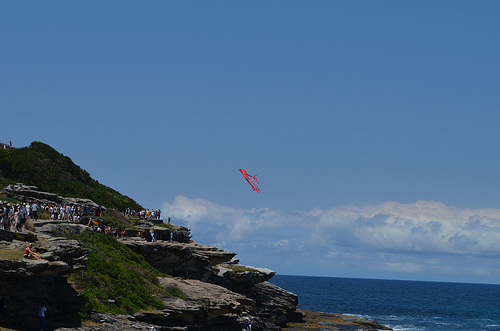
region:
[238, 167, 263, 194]
a red kite flying in the air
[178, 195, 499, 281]
some white clouds floating in the air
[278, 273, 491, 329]
the ocean next to the hill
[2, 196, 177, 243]
people standing around watching the kite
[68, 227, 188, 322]
the green grass on the hill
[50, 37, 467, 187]
a bunch of blue sky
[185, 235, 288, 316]
the rocks sticking out of the hill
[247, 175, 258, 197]
the long tail of the kite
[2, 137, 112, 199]
the top of the hill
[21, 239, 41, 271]
a person sitting on the hill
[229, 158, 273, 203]
red kite flying in sky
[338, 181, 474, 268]
large white cloud in blue sky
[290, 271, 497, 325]
blue water of ocean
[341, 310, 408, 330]
white wave in blue ocean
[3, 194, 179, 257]
group of people on rock formation in front of ocean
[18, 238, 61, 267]
person sitting alone on rock facing ocean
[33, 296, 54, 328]
person in rock cavern in front of ocean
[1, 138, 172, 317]
tall grass covered rock formation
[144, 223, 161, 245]
person on rock formation walking away from ocean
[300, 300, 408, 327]
flat land plateau in front of ocean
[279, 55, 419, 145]
The sky is blue.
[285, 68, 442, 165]
The sky is clear.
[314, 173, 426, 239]
Clouds are in the sky.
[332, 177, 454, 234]
The clouds are blue and white.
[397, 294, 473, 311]
The water is blue.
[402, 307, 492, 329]
Foam is in the water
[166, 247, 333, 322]
Rocks are showing.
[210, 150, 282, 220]
A kite is flying.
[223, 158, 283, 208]
The kie is red.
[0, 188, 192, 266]
People are watching.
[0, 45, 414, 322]
people on top of cliff by water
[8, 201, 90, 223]
large group of people standing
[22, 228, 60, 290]
person laying on top of cliff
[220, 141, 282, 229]
red kite being flown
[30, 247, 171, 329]
grass on side of cliff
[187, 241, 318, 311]
rock jettisoned out from cliff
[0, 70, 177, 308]
cliff mixed with grassy hill behind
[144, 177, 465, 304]
clouds in background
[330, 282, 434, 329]
blue ocean water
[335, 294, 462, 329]
white water from waves breaking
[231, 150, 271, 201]
red kite flying in blue sky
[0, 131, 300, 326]
people standing on cliffs watching a kite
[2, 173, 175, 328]
many people on cliff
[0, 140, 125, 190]
forest on top of cliff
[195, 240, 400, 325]
large cliff over the ocean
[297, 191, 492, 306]
clouds over the ocean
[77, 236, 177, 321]
grass growing on the cliffs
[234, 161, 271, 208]
red streamer flying in the sky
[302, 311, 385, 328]
brown rocks over the ocean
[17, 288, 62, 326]
man standing in the cave